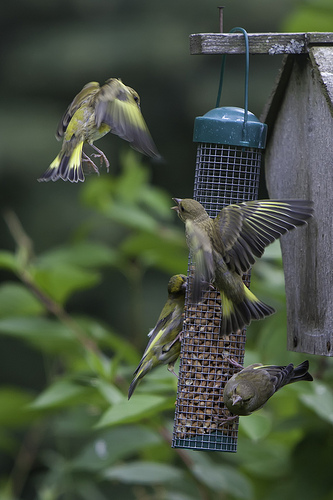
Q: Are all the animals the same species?
A: Yes, all the animals are birds.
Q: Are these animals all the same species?
A: Yes, all the animals are birds.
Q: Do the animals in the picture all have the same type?
A: Yes, all the animals are birds.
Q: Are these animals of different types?
A: No, all the animals are birds.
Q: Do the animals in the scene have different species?
A: No, all the animals are birds.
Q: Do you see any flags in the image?
A: No, there are no flags.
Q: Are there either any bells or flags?
A: No, there are no flags or bells.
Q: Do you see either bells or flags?
A: No, there are no flags or bells.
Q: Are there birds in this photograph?
A: Yes, there is a bird.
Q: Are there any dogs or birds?
A: Yes, there is a bird.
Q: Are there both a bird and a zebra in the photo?
A: No, there is a bird but no zebras.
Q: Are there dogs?
A: No, there are no dogs.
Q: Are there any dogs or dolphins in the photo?
A: No, there are no dogs or dolphins.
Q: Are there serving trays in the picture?
A: No, there are no serving trays.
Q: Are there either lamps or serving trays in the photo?
A: No, there are no serving trays or lamps.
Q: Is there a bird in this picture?
A: Yes, there is a bird.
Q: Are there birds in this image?
A: Yes, there is a bird.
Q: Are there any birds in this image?
A: Yes, there is a bird.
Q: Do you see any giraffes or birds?
A: Yes, there is a bird.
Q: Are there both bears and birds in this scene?
A: No, there is a bird but no bears.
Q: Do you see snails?
A: No, there are no snails.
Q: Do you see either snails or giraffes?
A: No, there are no snails or giraffes.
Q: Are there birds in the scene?
A: Yes, there is a bird.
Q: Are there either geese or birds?
A: Yes, there is a bird.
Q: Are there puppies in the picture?
A: No, there are no puppies.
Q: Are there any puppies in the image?
A: No, there are no puppies.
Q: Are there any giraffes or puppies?
A: No, there are no puppies or giraffes.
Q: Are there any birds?
A: Yes, there is a bird.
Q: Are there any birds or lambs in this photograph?
A: Yes, there is a bird.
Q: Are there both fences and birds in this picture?
A: No, there is a bird but no fences.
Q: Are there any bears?
A: No, there are no bears.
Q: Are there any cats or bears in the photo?
A: No, there are no bears or cats.